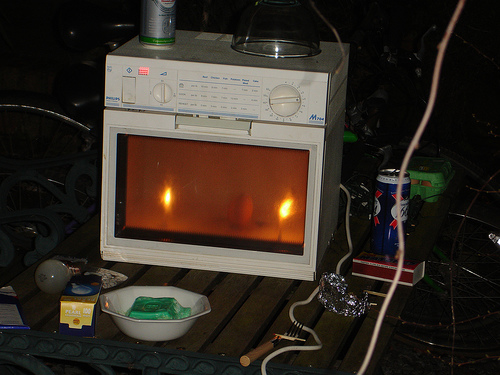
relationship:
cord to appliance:
[303, 185, 425, 357] [95, 27, 351, 284]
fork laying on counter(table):
[239, 318, 304, 365] [0, 152, 459, 373]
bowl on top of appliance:
[227, 2, 322, 62] [95, 27, 351, 284]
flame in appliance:
[159, 184, 176, 212] [95, 27, 351, 284]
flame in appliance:
[274, 191, 295, 223] [95, 27, 351, 284]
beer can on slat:
[371, 170, 411, 265] [287, 151, 435, 371]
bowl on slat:
[85, 247, 218, 346] [79, 260, 182, 340]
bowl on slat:
[85, 247, 218, 346] [156, 272, 259, 354]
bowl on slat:
[85, 247, 218, 346] [117, 270, 221, 350]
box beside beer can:
[401, 150, 456, 206] [365, 159, 414, 264]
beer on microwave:
[135, 0, 185, 52] [83, 38, 338, 275]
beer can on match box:
[371, 170, 411, 265] [348, 252, 427, 293]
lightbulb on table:
[7, 244, 107, 310] [27, 143, 392, 368]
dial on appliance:
[268, 85, 301, 117] [99, 28, 348, 281]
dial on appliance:
[152, 81, 173, 101] [99, 28, 348, 281]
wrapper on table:
[1, 279, 46, 362] [0, 111, 495, 368]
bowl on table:
[98, 285, 211, 341] [32, 141, 444, 371]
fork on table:
[239, 318, 304, 365] [212, 277, 376, 373]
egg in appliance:
[219, 193, 256, 237] [99, 28, 348, 281]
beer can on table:
[371, 170, 411, 265] [286, 249, 413, 334]